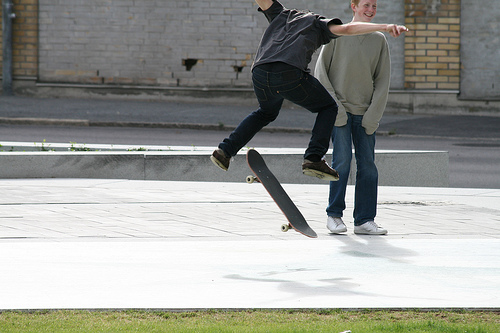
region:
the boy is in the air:
[208, 2, 409, 179]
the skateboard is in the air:
[246, 149, 316, 244]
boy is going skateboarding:
[209, 5, 406, 185]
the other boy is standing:
[318, 5, 393, 237]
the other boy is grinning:
[318, 2, 386, 22]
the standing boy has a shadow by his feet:
[317, 3, 421, 268]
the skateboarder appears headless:
[208, 0, 410, 178]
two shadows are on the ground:
[222, 232, 420, 308]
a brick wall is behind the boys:
[5, 0, 499, 112]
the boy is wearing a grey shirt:
[316, 21, 393, 131]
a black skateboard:
[247, 147, 322, 239]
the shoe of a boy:
[327, 212, 345, 233]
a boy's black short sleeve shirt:
[252, 2, 342, 68]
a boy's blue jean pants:
[325, 116, 377, 225]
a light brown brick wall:
[402, 0, 464, 89]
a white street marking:
[0, 132, 452, 158]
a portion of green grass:
[1, 308, 498, 331]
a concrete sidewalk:
[0, 235, 497, 305]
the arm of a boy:
[330, 18, 390, 35]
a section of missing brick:
[181, 53, 197, 71]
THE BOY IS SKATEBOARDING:
[239, 145, 317, 242]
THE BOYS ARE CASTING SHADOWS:
[217, 226, 417, 311]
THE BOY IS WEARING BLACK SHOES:
[206, 138, 346, 188]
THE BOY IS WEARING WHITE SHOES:
[322, 210, 388, 242]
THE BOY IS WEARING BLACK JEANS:
[214, 56, 343, 176]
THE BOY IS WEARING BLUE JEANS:
[321, 102, 381, 227]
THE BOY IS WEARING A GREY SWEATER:
[313, 20, 397, 144]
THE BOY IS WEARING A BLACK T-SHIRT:
[248, 0, 354, 80]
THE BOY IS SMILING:
[360, 7, 375, 23]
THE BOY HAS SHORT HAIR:
[352, 0, 367, 7]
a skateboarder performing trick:
[207, 0, 400, 247]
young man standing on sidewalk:
[315, 2, 402, 243]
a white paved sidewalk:
[0, 175, 498, 302]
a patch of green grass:
[2, 303, 494, 330]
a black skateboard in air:
[234, 145, 319, 242]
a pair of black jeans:
[214, 56, 334, 163]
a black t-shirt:
[255, 2, 336, 72]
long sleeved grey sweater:
[321, 23, 390, 130]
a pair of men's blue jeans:
[326, 110, 381, 222]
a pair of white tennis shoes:
[323, 212, 392, 239]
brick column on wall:
[401, 2, 461, 97]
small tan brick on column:
[436, 82, 458, 91]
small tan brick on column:
[413, 82, 438, 91]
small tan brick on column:
[435, 68, 458, 75]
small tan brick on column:
[413, 69, 436, 75]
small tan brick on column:
[426, 47, 448, 56]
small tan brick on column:
[414, 42, 436, 48]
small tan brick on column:
[413, 30, 435, 37]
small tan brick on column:
[426, 25, 445, 30]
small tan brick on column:
[438, 15, 459, 23]